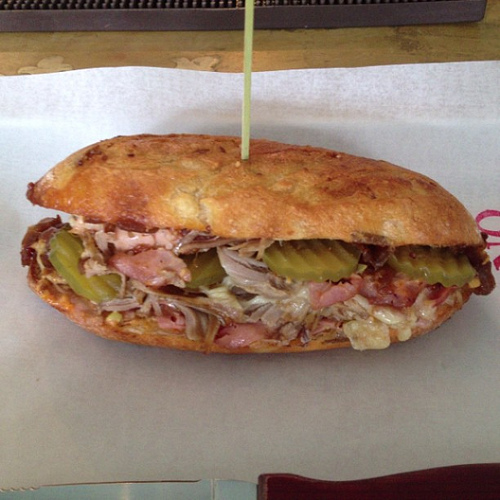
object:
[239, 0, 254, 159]
stick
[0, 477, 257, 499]
blade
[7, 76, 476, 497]
paper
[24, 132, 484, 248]
toasted bun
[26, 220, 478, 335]
toasted bun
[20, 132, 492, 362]
sandwich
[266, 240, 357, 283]
pickles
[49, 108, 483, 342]
sub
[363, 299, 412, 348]
cheese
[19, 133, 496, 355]
sandwich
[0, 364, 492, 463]
countertop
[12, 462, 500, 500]
knife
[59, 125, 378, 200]
toasted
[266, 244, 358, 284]
sandwich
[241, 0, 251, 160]
green pick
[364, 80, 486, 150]
sheet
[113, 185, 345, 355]
sub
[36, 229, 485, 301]
pickles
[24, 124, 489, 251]
bread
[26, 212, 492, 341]
meaty filling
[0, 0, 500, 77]
table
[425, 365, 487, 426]
background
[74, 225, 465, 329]
meat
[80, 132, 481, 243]
brown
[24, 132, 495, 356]
bread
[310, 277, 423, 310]
pulled pork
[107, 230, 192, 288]
pulled pork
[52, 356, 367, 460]
white paper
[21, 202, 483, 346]
meat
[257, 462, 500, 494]
handle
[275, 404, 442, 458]
section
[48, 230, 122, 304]
pickle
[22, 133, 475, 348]
sub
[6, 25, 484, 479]
table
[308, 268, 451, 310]
pork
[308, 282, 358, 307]
ham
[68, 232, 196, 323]
cheese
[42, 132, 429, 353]
sandwich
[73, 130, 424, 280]
sandwich bun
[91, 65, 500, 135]
paper